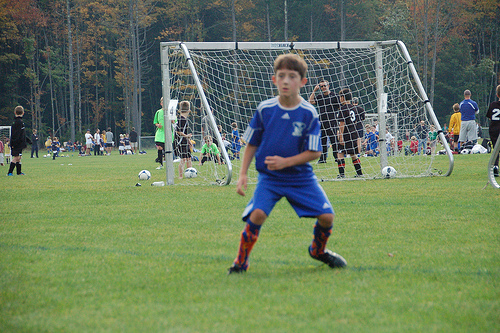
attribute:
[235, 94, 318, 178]
teeshirt — blue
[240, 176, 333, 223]
shorts — blue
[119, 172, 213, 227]
ground — green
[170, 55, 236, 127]
net — white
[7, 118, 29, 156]
uniform — black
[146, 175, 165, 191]
bottle — empty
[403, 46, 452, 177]
pole — white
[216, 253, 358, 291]
shoes — black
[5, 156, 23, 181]
socks — black